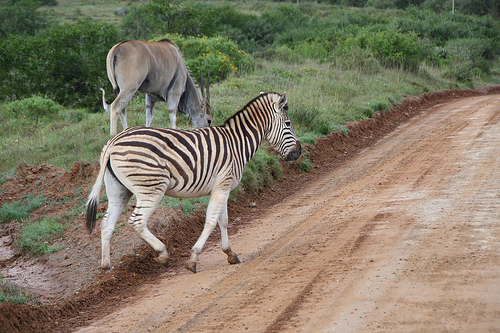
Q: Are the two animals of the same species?
A: No, they are antelopes and zebras.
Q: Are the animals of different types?
A: Yes, they are antelopes and zebras.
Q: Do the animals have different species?
A: Yes, they are antelopes and zebras.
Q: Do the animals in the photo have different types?
A: Yes, they are antelopes and zebras.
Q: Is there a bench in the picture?
A: No, there are no benches.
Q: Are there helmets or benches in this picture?
A: No, there are no benches or helmets.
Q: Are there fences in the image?
A: No, there are no fences.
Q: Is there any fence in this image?
A: No, there are no fences.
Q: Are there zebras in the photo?
A: Yes, there is a zebra.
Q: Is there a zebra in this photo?
A: Yes, there is a zebra.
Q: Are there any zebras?
A: Yes, there is a zebra.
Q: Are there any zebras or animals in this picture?
A: Yes, there is a zebra.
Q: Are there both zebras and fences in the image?
A: No, there is a zebra but no fences.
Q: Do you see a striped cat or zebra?
A: Yes, there is a striped zebra.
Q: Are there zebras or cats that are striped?
A: Yes, the zebra is striped.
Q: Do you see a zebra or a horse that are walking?
A: Yes, the zebra is walking.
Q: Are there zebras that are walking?
A: Yes, there is a zebra that is walking.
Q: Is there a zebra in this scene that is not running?
A: Yes, there is a zebra that is walking.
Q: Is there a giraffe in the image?
A: No, there are no giraffes.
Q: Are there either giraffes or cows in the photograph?
A: No, there are no giraffes or cows.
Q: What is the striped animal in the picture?
A: The animal is a zebra.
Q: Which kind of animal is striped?
A: The animal is a zebra.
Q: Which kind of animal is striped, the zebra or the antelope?
A: The zebra is striped.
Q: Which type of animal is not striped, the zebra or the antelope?
A: The antelope is not striped.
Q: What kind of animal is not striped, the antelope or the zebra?
A: The antelope is not striped.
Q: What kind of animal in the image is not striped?
A: The animal is an antelope.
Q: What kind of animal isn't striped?
A: The animal is an antelope.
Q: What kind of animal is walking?
A: The animal is a zebra.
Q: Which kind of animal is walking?
A: The animal is a zebra.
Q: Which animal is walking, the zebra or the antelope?
A: The zebra is walking.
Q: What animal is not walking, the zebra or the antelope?
A: The antelope is not walking.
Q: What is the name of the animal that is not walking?
A: The animal is an antelope.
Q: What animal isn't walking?
A: The animal is an antelope.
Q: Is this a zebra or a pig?
A: This is a zebra.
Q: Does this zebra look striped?
A: Yes, the zebra is striped.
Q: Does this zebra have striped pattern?
A: Yes, the zebra is striped.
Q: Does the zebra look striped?
A: Yes, the zebra is striped.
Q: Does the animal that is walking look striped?
A: Yes, the zebra is striped.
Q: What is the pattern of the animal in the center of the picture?
A: The zebra is striped.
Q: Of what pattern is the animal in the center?
A: The zebra is striped.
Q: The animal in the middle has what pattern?
A: The zebra is striped.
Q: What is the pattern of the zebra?
A: The zebra is striped.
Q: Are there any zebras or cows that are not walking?
A: No, there is a zebra but it is walking.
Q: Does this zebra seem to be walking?
A: Yes, the zebra is walking.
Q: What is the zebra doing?
A: The zebra is walking.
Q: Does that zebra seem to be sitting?
A: No, the zebra is walking.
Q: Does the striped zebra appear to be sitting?
A: No, the zebra is walking.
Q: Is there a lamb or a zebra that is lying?
A: No, there is a zebra but it is walking.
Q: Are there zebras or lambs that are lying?
A: No, there is a zebra but it is walking.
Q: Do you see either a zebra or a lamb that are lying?
A: No, there is a zebra but it is walking.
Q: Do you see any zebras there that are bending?
A: No, there is a zebra but it is walking.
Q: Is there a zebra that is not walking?
A: No, there is a zebra but it is walking.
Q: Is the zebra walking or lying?
A: The zebra is walking.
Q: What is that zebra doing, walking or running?
A: The zebra is walking.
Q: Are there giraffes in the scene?
A: No, there are no giraffes.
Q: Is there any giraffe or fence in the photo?
A: No, there are no giraffes or fences.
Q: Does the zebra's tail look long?
A: Yes, the tail is long.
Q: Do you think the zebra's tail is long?
A: Yes, the tail is long.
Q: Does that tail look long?
A: Yes, the tail is long.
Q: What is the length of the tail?
A: The tail is long.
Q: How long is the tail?
A: The tail is long.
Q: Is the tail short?
A: No, the tail is long.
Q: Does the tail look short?
A: No, the tail is long.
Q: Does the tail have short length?
A: No, the tail is long.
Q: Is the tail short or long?
A: The tail is long.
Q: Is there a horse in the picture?
A: No, there are no horses.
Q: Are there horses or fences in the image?
A: No, there are no horses or fences.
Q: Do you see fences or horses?
A: No, there are no horses or fences.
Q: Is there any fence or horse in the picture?
A: No, there are no horses or fences.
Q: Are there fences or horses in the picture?
A: No, there are no horses or fences.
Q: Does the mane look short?
A: Yes, the mane is short.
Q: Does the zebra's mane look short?
A: Yes, the mane is short.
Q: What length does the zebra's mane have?
A: The mane has short length.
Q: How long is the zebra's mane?
A: The mane is short.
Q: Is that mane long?
A: No, the mane is short.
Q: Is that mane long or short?
A: The mane is short.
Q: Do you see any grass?
A: Yes, there is grass.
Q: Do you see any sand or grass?
A: Yes, there is grass.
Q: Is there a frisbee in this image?
A: No, there are no frisbees.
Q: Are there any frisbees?
A: No, there are no frisbees.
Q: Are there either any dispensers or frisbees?
A: No, there are no frisbees or dispensers.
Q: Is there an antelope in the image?
A: Yes, there is an antelope.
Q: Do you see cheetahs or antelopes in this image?
A: Yes, there is an antelope.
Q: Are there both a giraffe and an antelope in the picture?
A: No, there is an antelope but no giraffes.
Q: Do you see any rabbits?
A: No, there are no rabbits.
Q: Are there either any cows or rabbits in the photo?
A: No, there are no rabbits or cows.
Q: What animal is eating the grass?
A: The antelope is eating the grass.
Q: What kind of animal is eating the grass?
A: The animal is an antelope.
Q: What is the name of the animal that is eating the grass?
A: The animal is an antelope.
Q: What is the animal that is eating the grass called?
A: The animal is an antelope.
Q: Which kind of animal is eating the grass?
A: The animal is an antelope.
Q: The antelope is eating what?
A: The antelope is eating grass.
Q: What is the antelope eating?
A: The antelope is eating grass.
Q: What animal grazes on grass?
A: The antelope grazes on grass.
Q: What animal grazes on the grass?
A: The antelope grazes on grass.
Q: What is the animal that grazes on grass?
A: The animal is an antelope.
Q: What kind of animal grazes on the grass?
A: The animal is an antelope.